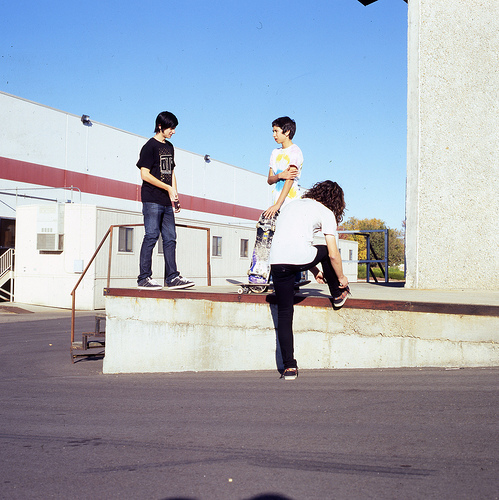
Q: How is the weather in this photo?
A: It is clear.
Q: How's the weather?
A: It is clear.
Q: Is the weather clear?
A: Yes, it is clear.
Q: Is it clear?
A: Yes, it is clear.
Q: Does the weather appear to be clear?
A: Yes, it is clear.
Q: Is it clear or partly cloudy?
A: It is clear.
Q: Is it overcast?
A: No, it is clear.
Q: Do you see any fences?
A: No, there are no fences.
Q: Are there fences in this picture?
A: No, there are no fences.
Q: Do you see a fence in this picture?
A: No, there are no fences.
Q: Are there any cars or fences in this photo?
A: No, there are no fences or cars.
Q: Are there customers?
A: No, there are no customers.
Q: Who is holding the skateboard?
A: The boy is holding the skateboard.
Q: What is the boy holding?
A: The boy is holding the skateboard.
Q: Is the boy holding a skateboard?
A: Yes, the boy is holding a skateboard.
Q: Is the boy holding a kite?
A: No, the boy is holding a skateboard.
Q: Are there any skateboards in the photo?
A: Yes, there is a skateboard.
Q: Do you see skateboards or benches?
A: Yes, there is a skateboard.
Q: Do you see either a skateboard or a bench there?
A: Yes, there is a skateboard.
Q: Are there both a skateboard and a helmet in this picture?
A: No, there is a skateboard but no helmets.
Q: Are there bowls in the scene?
A: No, there are no bowls.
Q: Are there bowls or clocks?
A: No, there are no bowls or clocks.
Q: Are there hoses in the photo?
A: No, there are no hoses.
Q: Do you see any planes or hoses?
A: No, there are no hoses or planes.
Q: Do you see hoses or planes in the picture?
A: No, there are no hoses or planes.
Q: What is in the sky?
A: The clouds are in the sky.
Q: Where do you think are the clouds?
A: The clouds are in the sky.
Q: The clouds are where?
A: The clouds are in the sky.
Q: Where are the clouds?
A: The clouds are in the sky.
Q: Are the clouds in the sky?
A: Yes, the clouds are in the sky.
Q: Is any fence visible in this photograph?
A: No, there are no fences.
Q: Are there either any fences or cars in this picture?
A: No, there are no fences or cars.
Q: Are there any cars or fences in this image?
A: No, there are no fences or cars.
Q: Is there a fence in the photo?
A: No, there are no fences.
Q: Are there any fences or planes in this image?
A: No, there are no fences or planes.